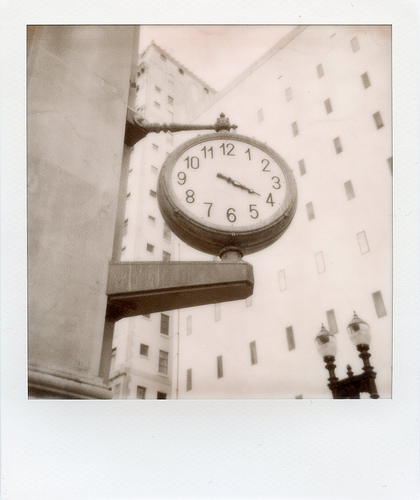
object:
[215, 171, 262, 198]
hand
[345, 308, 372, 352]
lamp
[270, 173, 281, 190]
number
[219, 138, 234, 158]
number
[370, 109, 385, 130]
window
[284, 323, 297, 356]
window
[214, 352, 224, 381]
window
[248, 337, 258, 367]
window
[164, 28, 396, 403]
building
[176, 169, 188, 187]
black 9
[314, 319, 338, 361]
lamp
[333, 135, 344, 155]
window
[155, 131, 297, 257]
clock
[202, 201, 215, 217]
number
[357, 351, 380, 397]
posts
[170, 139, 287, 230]
face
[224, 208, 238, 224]
6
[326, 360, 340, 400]
pole